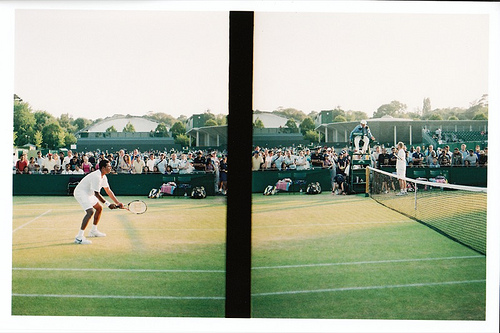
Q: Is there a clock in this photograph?
A: No, there are no clocks.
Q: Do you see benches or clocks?
A: No, there are no clocks or benches.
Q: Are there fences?
A: No, there are no fences.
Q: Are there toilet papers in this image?
A: No, there are no toilet papers.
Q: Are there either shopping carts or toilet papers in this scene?
A: No, there are no toilet papers or shopping carts.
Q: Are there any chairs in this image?
A: Yes, there is a chair.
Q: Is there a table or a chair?
A: Yes, there is a chair.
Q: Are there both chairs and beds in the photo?
A: No, there is a chair but no beds.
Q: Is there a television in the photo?
A: No, there are no televisions.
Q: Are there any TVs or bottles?
A: No, there are no TVs or bottles.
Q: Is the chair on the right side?
A: Yes, the chair is on the right of the image.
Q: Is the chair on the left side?
A: No, the chair is on the right of the image.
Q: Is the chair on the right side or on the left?
A: The chair is on the right of the image.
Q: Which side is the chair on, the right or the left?
A: The chair is on the right of the image.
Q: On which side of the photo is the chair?
A: The chair is on the right of the image.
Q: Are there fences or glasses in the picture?
A: No, there are no fences or glasses.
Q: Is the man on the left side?
A: Yes, the man is on the left of the image.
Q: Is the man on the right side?
A: No, the man is on the left of the image.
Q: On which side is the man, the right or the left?
A: The man is on the left of the image.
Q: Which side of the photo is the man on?
A: The man is on the left of the image.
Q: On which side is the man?
A: The man is on the left of the image.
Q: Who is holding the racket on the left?
A: The man is holding the tennis racket.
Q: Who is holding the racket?
A: The man is holding the tennis racket.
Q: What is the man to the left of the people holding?
A: The man is holding the racket.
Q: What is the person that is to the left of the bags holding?
A: The man is holding the racket.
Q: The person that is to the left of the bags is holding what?
A: The man is holding the racket.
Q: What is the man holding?
A: The man is holding the racket.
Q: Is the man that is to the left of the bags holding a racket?
A: Yes, the man is holding a racket.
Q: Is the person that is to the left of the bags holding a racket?
A: Yes, the man is holding a racket.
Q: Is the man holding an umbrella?
A: No, the man is holding a racket.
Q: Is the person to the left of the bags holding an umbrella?
A: No, the man is holding a racket.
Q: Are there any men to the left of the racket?
A: Yes, there is a man to the left of the racket.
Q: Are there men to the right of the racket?
A: No, the man is to the left of the racket.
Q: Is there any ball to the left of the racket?
A: No, there is a man to the left of the racket.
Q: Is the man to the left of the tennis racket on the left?
A: Yes, the man is to the left of the tennis racket.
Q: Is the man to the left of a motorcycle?
A: No, the man is to the left of the tennis racket.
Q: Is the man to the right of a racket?
A: No, the man is to the left of a racket.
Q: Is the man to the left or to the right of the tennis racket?
A: The man is to the left of the tennis racket.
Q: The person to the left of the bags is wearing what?
A: The man is wearing shoes.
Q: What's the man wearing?
A: The man is wearing shoes.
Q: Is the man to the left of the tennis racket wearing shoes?
A: Yes, the man is wearing shoes.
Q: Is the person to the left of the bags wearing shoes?
A: Yes, the man is wearing shoes.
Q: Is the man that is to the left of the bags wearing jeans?
A: No, the man is wearing shoes.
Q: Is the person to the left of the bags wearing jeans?
A: No, the man is wearing shoes.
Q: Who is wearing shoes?
A: The man is wearing shoes.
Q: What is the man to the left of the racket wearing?
A: The man is wearing shoes.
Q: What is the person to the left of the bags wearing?
A: The man is wearing shoes.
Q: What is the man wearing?
A: The man is wearing shoes.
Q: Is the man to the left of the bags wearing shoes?
A: Yes, the man is wearing shoes.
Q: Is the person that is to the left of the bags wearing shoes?
A: Yes, the man is wearing shoes.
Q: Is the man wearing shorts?
A: No, the man is wearing shoes.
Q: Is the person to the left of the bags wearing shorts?
A: No, the man is wearing shoes.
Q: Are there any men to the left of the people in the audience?
A: Yes, there is a man to the left of the people.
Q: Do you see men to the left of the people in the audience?
A: Yes, there is a man to the left of the people.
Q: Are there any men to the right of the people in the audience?
A: No, the man is to the left of the people.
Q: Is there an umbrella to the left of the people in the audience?
A: No, there is a man to the left of the people.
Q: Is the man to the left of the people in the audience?
A: Yes, the man is to the left of the people.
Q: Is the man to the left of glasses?
A: No, the man is to the left of the people.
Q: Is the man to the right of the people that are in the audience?
A: No, the man is to the left of the people.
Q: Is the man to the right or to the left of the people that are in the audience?
A: The man is to the left of the people.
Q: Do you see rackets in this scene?
A: Yes, there is a racket.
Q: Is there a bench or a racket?
A: Yes, there is a racket.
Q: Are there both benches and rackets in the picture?
A: No, there is a racket but no benches.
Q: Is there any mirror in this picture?
A: No, there are no mirrors.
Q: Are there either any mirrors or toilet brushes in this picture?
A: No, there are no mirrors or toilet brushes.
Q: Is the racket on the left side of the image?
A: Yes, the racket is on the left of the image.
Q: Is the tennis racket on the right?
A: No, the tennis racket is on the left of the image.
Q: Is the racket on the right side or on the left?
A: The racket is on the left of the image.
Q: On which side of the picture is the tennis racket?
A: The tennis racket is on the left of the image.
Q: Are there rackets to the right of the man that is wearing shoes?
A: Yes, there is a racket to the right of the man.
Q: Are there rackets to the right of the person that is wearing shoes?
A: Yes, there is a racket to the right of the man.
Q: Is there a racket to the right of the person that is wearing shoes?
A: Yes, there is a racket to the right of the man.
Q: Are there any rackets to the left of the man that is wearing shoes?
A: No, the racket is to the right of the man.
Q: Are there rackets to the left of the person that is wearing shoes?
A: No, the racket is to the right of the man.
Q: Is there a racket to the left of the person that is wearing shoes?
A: No, the racket is to the right of the man.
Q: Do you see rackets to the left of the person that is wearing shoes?
A: No, the racket is to the right of the man.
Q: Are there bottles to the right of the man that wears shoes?
A: No, there is a racket to the right of the man.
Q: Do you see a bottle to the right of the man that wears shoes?
A: No, there is a racket to the right of the man.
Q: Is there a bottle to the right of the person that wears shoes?
A: No, there is a racket to the right of the man.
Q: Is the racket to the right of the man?
A: Yes, the racket is to the right of the man.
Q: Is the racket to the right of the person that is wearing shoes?
A: Yes, the racket is to the right of the man.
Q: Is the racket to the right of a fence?
A: No, the racket is to the right of the man.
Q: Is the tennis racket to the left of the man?
A: No, the tennis racket is to the right of the man.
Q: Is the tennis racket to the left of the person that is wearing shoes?
A: No, the tennis racket is to the right of the man.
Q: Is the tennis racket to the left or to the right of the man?
A: The tennis racket is to the right of the man.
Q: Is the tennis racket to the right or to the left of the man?
A: The tennis racket is to the right of the man.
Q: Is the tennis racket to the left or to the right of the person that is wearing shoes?
A: The tennis racket is to the right of the man.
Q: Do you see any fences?
A: No, there are no fences.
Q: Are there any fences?
A: No, there are no fences.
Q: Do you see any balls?
A: No, there are no balls.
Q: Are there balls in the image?
A: No, there are no balls.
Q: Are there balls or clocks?
A: No, there are no balls or clocks.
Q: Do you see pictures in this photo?
A: No, there are no pictures.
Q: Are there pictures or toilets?
A: No, there are no pictures or toilets.